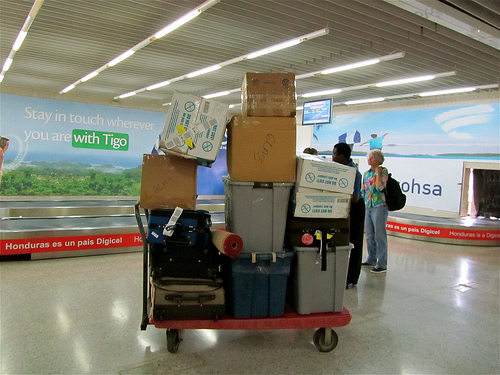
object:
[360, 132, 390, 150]
boy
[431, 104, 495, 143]
cloud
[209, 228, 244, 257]
mat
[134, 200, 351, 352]
trolley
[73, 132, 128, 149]
lettering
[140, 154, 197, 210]
box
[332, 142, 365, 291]
man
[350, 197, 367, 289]
pants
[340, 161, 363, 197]
shirt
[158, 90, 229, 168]
box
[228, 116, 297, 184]
box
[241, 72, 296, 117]
box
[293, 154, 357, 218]
box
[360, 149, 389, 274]
woman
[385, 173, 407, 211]
backpack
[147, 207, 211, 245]
suitcase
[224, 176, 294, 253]
bin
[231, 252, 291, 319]
bin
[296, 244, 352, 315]
bin